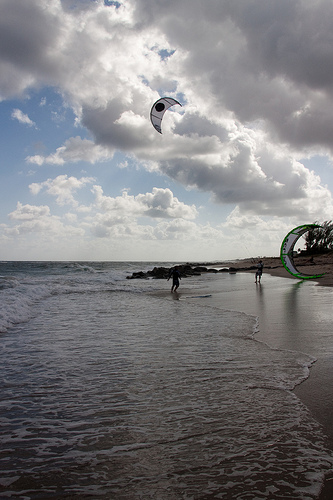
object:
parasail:
[149, 97, 182, 134]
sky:
[0, 0, 333, 263]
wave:
[1, 283, 138, 333]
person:
[254, 260, 263, 283]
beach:
[159, 260, 332, 425]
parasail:
[280, 224, 327, 280]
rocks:
[126, 264, 237, 280]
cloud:
[0, 0, 333, 220]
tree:
[305, 220, 333, 254]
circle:
[155, 103, 165, 113]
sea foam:
[43, 397, 169, 479]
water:
[0, 260, 314, 498]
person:
[167, 266, 181, 294]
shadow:
[286, 280, 304, 315]